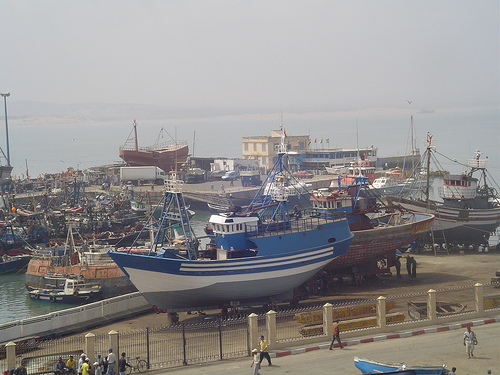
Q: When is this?
A: Daytime.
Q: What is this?
A: A ship.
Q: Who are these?
A: People.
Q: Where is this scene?
A: At a marina.